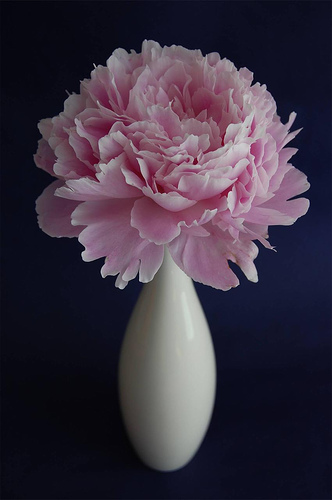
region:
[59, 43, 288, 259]
pink petals of a flower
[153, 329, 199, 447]
white glossy surface of the vase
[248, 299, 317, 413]
blue wall of the room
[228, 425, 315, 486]
blue surface of the table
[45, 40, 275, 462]
a pink flower in a white vase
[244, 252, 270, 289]
white edges of the pink flower petals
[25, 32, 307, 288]
a blooming pink flower head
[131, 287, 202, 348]
reflections of light on the vase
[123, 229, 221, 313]
slim neck of the vase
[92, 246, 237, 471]
a white vase shaped like a bowling pin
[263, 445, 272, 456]
part of a surface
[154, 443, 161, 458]
edge of a vase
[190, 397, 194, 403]
side of a vase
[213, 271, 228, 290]
part of a flower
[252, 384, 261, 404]
side of a surface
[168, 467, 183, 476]
bottom of a jug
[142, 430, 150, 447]
side of a jug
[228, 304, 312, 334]
solid blue surface in the background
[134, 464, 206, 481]
surface under white vase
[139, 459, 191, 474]
base of white vase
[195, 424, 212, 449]
curved edge on vase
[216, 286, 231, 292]
tip of pink petal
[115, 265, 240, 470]
tall white vase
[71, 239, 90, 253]
curve in flower petal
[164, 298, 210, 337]
shine on white vase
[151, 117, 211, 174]
inside of the flower petals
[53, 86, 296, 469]
large white vase filled with flowers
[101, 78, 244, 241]
A pink flower in a vase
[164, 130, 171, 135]
The centre of the flower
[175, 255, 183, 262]
The whorl touching the vase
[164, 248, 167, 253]
Vase visible between two whorls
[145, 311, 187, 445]
The flower vase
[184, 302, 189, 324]
Reflection of light on vase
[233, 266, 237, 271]
Background between two whorls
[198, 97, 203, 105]
Shadow inside the flower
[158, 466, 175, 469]
The base of the vase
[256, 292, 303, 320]
Dark blue background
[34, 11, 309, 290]
pink peony flower with white tips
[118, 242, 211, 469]
slender and curved white vase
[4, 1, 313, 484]
black background behind flower display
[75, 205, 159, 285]
curved edges of petal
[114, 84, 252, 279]
layers of petals forming flower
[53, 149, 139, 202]
petal edges curving upward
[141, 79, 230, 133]
dense cluster of petals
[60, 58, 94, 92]
points on edge of petals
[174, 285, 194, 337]
rectangle of light reflecting off vase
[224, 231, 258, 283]
small petal with brown lines